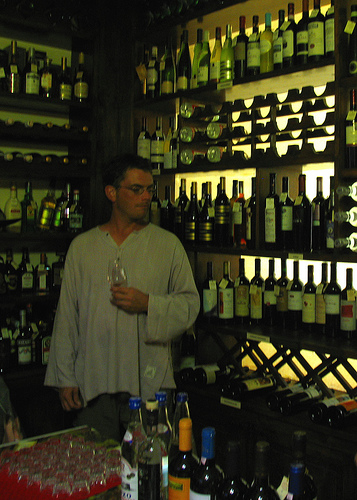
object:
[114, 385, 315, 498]
bottle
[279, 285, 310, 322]
label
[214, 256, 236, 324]
bottle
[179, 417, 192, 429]
cap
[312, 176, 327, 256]
bottle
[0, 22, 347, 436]
shelf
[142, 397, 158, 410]
cap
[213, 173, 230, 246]
wine bottle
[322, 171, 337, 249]
bottles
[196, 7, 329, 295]
shelves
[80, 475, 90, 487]
glasses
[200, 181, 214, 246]
wine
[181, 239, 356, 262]
shelf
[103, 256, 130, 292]
empty glasses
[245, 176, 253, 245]
wine bottle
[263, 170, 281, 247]
wine bottle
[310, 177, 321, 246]
wine bottle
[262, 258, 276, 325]
wine bottle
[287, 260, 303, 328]
wine bottle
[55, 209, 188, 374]
shirt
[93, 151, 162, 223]
head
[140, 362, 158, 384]
tag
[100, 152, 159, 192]
hair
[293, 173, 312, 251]
wine bottle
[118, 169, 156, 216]
face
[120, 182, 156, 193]
glasses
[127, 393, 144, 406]
caps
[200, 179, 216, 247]
bottle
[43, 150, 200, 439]
man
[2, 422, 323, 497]
table